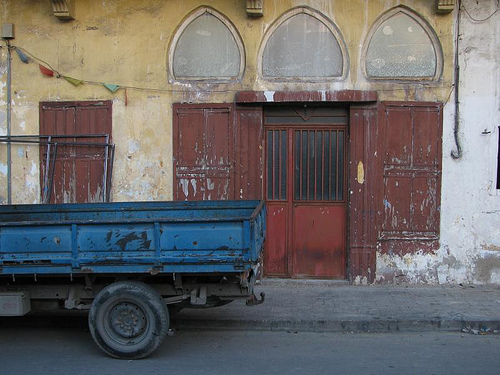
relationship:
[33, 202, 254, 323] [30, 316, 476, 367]
cart on road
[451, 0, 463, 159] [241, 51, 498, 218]
hook on wall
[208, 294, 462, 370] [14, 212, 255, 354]
sidewalk behind cart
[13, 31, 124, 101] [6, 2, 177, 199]
flags on wall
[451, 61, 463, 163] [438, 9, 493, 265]
hook on wall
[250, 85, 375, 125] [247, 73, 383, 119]
paint on door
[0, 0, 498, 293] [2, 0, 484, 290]
paint on building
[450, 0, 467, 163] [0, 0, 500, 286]
electric line coming out of wall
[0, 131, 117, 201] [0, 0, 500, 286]
frame by wall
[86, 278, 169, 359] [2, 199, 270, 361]
tire on pickup truck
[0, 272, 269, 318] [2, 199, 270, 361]
chassis on pickup truck